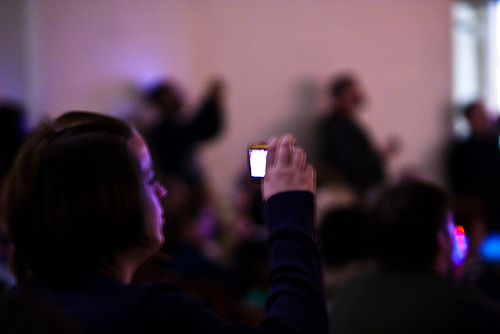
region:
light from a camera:
[247, 148, 266, 173]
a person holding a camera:
[29, 109, 329, 329]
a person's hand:
[262, 125, 327, 314]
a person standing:
[21, 102, 343, 327]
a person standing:
[309, 60, 398, 184]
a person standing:
[134, 68, 235, 212]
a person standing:
[434, 86, 497, 217]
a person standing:
[359, 187, 495, 332]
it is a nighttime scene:
[1, 0, 495, 326]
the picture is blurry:
[1, 1, 498, 332]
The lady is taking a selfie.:
[213, 124, 348, 209]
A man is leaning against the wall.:
[328, 53, 413, 198]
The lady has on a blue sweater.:
[39, 238, 331, 305]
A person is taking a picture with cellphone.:
[118, 61, 251, 227]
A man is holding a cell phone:
[431, 218, 483, 300]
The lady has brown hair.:
[16, 101, 155, 298]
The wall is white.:
[212, 8, 482, 119]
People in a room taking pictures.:
[50, 67, 461, 299]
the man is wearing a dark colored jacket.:
[297, 106, 404, 201]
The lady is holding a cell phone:
[236, 122, 362, 266]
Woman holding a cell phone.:
[232, 137, 304, 192]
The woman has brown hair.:
[4, 113, 171, 273]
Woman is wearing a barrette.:
[23, 107, 88, 155]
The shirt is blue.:
[110, 297, 181, 332]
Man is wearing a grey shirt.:
[381, 287, 451, 329]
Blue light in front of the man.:
[449, 232, 499, 277]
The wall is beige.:
[227, 22, 312, 69]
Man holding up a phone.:
[137, 69, 259, 167]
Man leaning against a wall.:
[311, 68, 417, 189]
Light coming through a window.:
[453, 27, 498, 114]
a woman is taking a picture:
[60, 85, 365, 315]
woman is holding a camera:
[58, 104, 281, 319]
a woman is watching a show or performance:
[1, 87, 403, 288]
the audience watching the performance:
[147, 55, 444, 276]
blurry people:
[271, 47, 423, 258]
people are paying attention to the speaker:
[148, 59, 459, 311]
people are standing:
[52, 24, 288, 263]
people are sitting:
[301, 95, 488, 293]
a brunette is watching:
[53, 97, 187, 288]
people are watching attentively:
[88, 82, 419, 332]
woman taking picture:
[248, 134, 313, 201]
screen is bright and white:
[228, 148, 298, 205]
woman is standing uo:
[10, 94, 337, 318]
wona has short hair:
[22, 115, 140, 296]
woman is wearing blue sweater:
[25, 191, 383, 326]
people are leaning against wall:
[125, 67, 439, 189]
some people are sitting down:
[328, 134, 475, 326]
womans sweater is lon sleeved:
[221, 155, 335, 275]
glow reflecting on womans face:
[120, 135, 192, 247]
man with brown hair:
[362, 162, 459, 322]